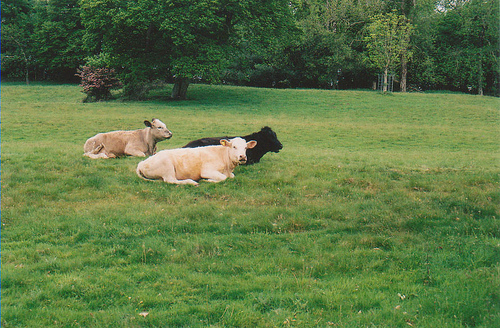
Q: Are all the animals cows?
A: Yes, all the animals are cows.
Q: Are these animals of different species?
A: No, all the animals are cows.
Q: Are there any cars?
A: No, there are no cars.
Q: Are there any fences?
A: Yes, there is a fence.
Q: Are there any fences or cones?
A: Yes, there is a fence.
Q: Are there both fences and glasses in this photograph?
A: No, there is a fence but no glasses.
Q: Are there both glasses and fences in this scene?
A: No, there is a fence but no glasses.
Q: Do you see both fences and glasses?
A: No, there is a fence but no glasses.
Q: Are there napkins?
A: No, there are no napkins.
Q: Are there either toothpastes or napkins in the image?
A: No, there are no napkins or toothpastes.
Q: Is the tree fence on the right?
A: Yes, the fence is on the right of the image.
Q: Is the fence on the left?
A: No, the fence is on the right of the image.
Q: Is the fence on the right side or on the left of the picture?
A: The fence is on the right of the image.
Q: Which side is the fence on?
A: The fence is on the right of the image.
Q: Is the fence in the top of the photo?
A: Yes, the fence is in the top of the image.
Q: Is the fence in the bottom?
A: No, the fence is in the top of the image.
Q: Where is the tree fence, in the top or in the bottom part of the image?
A: The fence is in the top of the image.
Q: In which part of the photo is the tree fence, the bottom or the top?
A: The fence is in the top of the image.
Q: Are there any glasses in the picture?
A: No, there are no glasses.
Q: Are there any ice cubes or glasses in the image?
A: No, there are no glasses or ice cubes.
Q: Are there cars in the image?
A: No, there are no cars.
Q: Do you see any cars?
A: No, there are no cars.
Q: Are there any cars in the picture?
A: No, there are no cars.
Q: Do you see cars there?
A: No, there are no cars.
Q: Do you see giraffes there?
A: No, there are no giraffes.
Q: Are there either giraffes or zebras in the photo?
A: No, there are no giraffes or zebras.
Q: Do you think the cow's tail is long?
A: Yes, the tail is long.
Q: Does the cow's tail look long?
A: Yes, the tail is long.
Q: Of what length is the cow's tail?
A: The tail is long.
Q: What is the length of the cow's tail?
A: The tail is long.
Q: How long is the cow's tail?
A: The tail is long.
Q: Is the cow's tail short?
A: No, the tail is long.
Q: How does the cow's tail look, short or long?
A: The tail is long.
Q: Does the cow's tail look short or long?
A: The tail is long.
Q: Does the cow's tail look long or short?
A: The tail is long.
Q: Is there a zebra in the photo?
A: No, there are no zebras.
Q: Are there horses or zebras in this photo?
A: No, there are no zebras or horses.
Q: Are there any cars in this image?
A: No, there are no cars.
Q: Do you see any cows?
A: Yes, there is a cow.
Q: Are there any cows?
A: Yes, there is a cow.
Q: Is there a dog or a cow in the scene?
A: Yes, there is a cow.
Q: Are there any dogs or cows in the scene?
A: Yes, there is a cow.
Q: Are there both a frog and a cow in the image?
A: No, there is a cow but no frogs.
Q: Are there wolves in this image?
A: No, there are no wolves.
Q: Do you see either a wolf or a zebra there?
A: No, there are no wolves or zebras.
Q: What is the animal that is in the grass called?
A: The animal is a cow.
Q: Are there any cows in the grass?
A: Yes, there is a cow in the grass.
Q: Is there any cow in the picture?
A: Yes, there is a cow.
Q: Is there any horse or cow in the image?
A: Yes, there is a cow.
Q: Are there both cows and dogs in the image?
A: No, there is a cow but no dogs.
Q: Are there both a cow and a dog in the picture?
A: No, there is a cow but no dogs.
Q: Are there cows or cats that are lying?
A: Yes, the cow is lying.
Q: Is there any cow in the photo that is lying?
A: Yes, there is a cow that is lying.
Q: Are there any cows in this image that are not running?
A: Yes, there is a cow that is lying.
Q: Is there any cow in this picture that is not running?
A: Yes, there is a cow that is lying.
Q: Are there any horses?
A: No, there are no horses.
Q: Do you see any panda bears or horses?
A: No, there are no horses or panda bears.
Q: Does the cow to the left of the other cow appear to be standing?
A: No, the cow is lying.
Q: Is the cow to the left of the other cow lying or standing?
A: The cow is lying.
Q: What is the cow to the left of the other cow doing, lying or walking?
A: The cow is lying.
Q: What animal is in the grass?
A: The animal is a cow.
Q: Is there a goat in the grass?
A: No, there is a cow in the grass.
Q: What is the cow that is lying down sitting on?
A: The cow is sitting on the grass.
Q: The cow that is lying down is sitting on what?
A: The cow is sitting on the grass.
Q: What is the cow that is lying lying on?
A: The cow is lying on the grass.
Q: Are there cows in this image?
A: Yes, there is a cow.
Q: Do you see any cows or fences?
A: Yes, there is a cow.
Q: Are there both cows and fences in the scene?
A: Yes, there are both a cow and a fence.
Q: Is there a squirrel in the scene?
A: No, there are no squirrels.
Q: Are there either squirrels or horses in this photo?
A: No, there are no squirrels or horses.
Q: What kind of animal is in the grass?
A: The animal is a cow.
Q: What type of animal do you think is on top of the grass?
A: The animal is a cow.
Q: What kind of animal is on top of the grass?
A: The animal is a cow.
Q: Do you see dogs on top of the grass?
A: No, there is a cow on top of the grass.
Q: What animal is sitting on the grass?
A: The cow is sitting on the grass.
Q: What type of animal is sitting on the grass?
A: The animal is a cow.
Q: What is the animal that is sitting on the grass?
A: The animal is a cow.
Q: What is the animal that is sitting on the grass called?
A: The animal is a cow.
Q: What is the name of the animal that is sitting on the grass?
A: The animal is a cow.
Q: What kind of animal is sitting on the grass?
A: The animal is a cow.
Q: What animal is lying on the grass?
A: The cow is lying on the grass.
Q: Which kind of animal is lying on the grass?
A: The animal is a cow.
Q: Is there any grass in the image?
A: Yes, there is grass.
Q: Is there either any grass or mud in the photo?
A: Yes, there is grass.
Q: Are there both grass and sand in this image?
A: No, there is grass but no sand.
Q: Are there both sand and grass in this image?
A: No, there is grass but no sand.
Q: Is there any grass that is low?
A: Yes, there is low grass.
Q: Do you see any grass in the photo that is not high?
A: Yes, there is low grass.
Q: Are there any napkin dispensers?
A: No, there are no napkin dispensers.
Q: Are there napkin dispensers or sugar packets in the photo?
A: No, there are no napkin dispensers or sugar packets.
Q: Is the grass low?
A: Yes, the grass is low.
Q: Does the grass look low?
A: Yes, the grass is low.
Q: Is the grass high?
A: No, the grass is low.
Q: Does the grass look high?
A: No, the grass is low.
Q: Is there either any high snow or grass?
A: No, there is grass but it is low.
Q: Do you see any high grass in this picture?
A: No, there is grass but it is low.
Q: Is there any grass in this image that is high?
A: No, there is grass but it is low.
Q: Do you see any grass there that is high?
A: No, there is grass but it is low.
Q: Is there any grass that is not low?
A: No, there is grass but it is low.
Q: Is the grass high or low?
A: The grass is low.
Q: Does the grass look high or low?
A: The grass is low.